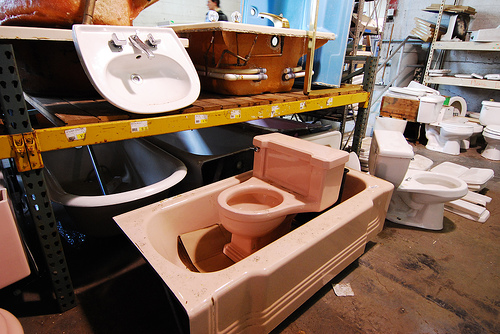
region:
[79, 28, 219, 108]
the sink is white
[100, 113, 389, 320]
a toilet in a tub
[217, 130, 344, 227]
The pink toilet inside of the bath tub.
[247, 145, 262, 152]
The flusher handle of the pink toilet.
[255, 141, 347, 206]
The water tank of the pink toilet.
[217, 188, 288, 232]
The toilet bowl of the pink toilet.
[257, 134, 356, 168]
The lid of the water tank on the pink toilet.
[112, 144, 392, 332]
The tub the pink toilet is placed in.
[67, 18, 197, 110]
The white sink on the shelf.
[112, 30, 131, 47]
The left knob of the sink on the shelf.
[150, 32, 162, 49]
The right knob of the sink on the shelf.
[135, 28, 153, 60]
The faucet of the sink on the shelf.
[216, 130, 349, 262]
the toilet is peach colored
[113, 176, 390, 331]
the bathtub is peach colored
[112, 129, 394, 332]
the toilet is inside the bathtub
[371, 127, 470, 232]
the toilet is white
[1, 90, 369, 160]
the shelf is yellow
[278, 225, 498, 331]
the floor is brown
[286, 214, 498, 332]
the floor is made of wood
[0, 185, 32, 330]
this toilet is pink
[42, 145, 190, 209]
this bathtub is white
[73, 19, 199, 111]
the sink is white in color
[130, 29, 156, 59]
the faucet is made of metal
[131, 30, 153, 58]
the faucet is shiny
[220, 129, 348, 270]
the toilet is made of ceramic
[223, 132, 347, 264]
the toilet is pink in color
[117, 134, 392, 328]
the sink is in the bathtub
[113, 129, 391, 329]
the sink is pink in color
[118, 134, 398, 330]
the bathtub is pink in color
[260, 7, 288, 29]
the faucet is made of brass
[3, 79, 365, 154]
the shelf is made of wood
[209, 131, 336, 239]
a toilet that is not in use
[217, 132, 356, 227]
the toilet is tan in color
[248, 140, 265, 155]
handle of the toilet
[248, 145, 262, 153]
the handle is silver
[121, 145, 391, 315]
a bathtub not in use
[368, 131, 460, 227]
a white toilet on the ground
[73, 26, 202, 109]
a sink part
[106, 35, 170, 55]
the silver sink handles